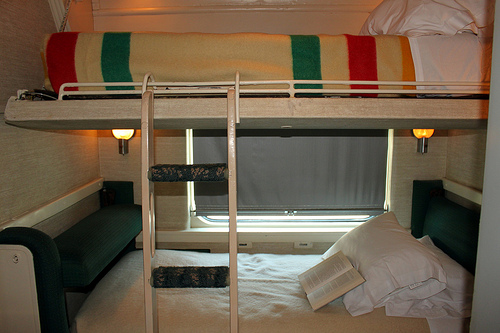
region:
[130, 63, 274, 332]
Ladder on side of bed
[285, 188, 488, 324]
Pillows on the bed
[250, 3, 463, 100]
The blanket is lined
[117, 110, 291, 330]
The ladder is made of metal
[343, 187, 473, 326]
The pillows are white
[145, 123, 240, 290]
Steps on the ladder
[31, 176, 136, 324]
Footboard on the bed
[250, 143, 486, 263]
The shade is pulled down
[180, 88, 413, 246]
Window on the wall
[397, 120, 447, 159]
Light on the wall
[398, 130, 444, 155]
light in corner of cabin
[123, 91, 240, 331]
ladder to the upper bunk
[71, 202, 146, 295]
green pillows on the bed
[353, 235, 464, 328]
white pillows on the bed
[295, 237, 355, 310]
book opened on pillow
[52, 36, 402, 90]
red white green on blanket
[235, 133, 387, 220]
shade on the window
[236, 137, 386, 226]
shade is gray on window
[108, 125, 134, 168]
light is bright on wall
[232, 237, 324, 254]
outlets on the wall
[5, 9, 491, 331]
a set of bunk beds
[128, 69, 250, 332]
a ladder for a bunk bed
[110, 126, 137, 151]
a light on the wall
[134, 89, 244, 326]
a white ladder with padded steps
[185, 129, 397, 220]
a shade on a window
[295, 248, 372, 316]
a book on a bed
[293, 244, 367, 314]
a book on a pillow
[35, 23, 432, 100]
a striped blanket on a bed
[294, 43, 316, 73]
green color in blanket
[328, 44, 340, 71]
yellow color in blanket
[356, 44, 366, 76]
red color in blanket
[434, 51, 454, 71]
white sheet under blanket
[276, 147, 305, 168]
grey shade on window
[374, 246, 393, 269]
white pillow on top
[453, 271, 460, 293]
white pillow on bottom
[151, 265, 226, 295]
first step to top bunk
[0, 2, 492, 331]
a bunker bed in a train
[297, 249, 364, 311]
an opened hardcover book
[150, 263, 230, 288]
fur on the step of a ladder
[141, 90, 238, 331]
a wooden ladder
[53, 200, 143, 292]
a green headrest in a train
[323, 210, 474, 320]
white pillow on a bed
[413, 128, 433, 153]
yellow light fixture on the wall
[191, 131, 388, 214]
a gray blind on the window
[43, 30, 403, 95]
a yellow blanket with red and green lines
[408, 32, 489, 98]
white sheet on a bed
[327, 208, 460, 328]
a pillow on the bed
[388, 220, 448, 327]
a pillow on the bed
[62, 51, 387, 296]
these are bunk beds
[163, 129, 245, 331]
this is a small ladder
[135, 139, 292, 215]
this is a ladder step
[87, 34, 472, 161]
the mattress is multicolored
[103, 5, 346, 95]
the sheets are yellow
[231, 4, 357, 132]
the stripes are green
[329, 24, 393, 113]
the stripes are red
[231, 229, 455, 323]
the pillows are white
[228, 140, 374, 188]
the window shade is gray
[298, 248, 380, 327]
a book is open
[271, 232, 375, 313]
an open book on the bed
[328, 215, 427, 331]
a pillow on the bed